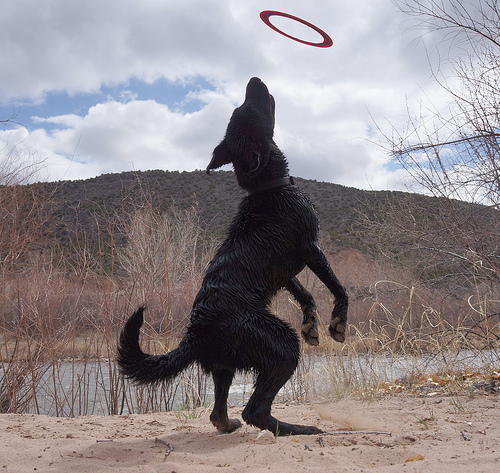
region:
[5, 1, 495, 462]
Exterior shot, most likely taken between, late fall and early spring.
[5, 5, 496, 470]
Daytime view, on overcast day, showing landscape and domesticated animal.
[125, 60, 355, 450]
Medium-sized black dog, standing on back paws.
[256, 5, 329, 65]
Ring that has been tossed, and is headed for dog.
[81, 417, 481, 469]
Sand with tracks in it.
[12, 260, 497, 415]
Tall, dried-out stalks, near water's edge.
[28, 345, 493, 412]
moderately small, body of water.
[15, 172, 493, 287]
Tree-covered mountain in distance.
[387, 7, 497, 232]
Tree branches without leaves.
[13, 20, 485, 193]
Blue sky, with dense, grey clouds.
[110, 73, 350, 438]
wet black furry dog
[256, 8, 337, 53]
red and black frisbee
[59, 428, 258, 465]
shadow cast by dog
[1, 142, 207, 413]
trees bare of leaves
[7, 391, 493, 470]
sand on lake shore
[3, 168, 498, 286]
mountain on other side of lake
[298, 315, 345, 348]
muddy pads on dog's paws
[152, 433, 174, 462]
twig laying in the sand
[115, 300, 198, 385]
dog's tail curled up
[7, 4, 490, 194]
large white puffy clouds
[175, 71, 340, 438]
black dog standing on hind legs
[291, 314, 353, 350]
black dog with sandy paws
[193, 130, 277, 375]
black dog with wet hair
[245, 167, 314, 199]
black dog with black collar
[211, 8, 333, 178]
black dog is looking up in the air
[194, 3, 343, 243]
black dog is trying to catch a circular toy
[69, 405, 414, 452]
black dog is standing on sandy soil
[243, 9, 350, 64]
red flying disc is in the air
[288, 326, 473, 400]
brown grass and weeds by dog's feet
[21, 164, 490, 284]
gray green hills in the background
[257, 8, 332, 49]
A round frisbee dog toy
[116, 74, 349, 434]
A black dog on it's back legs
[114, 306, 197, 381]
Black furry tail of a dog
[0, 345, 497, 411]
Water in the middle of the scene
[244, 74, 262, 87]
Black nose of a black dog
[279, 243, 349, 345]
Two front black paws on a dog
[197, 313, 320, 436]
Two black back legs of a dog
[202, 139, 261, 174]
Two pointy black ears of a dog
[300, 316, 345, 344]
Brown pads of a dogs feet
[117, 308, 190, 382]
Black tail of a dog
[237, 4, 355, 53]
A red frisbee in the air.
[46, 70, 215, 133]
A small patch of blue sky.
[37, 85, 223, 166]
Puffy white clouds in a blue sky.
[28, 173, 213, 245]
Mountain with green trees.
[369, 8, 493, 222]
A tree with bare branches.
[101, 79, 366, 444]
Black dog jumping for a frisbee.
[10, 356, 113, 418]
A river with running water.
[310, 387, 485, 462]
Dog jumpin in the sand.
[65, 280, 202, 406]
Tail of a black dog.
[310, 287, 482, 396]
Swamp grass in the sand.